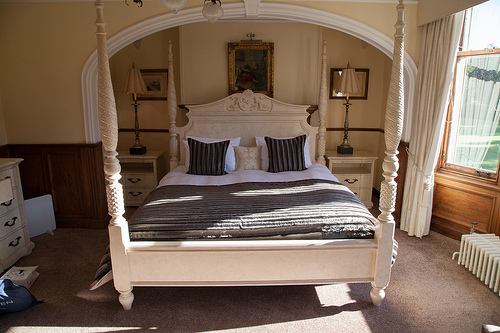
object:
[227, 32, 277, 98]
framed picture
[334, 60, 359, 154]
tall lamps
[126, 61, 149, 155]
tall lamps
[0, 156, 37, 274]
dresser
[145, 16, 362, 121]
wall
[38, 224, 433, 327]
street scene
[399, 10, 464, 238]
drapes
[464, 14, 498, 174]
window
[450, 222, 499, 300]
heater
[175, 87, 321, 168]
headboard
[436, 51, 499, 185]
windows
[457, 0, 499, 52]
window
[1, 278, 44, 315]
clutter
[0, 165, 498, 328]
floor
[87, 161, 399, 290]
comforter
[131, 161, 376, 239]
mattress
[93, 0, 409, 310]
bed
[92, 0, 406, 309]
bed frame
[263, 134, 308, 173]
pillow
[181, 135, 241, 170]
pillow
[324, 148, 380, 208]
end table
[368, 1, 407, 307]
posts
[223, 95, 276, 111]
design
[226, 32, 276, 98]
frame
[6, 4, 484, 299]
bedroom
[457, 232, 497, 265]
pipe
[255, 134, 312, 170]
pillow